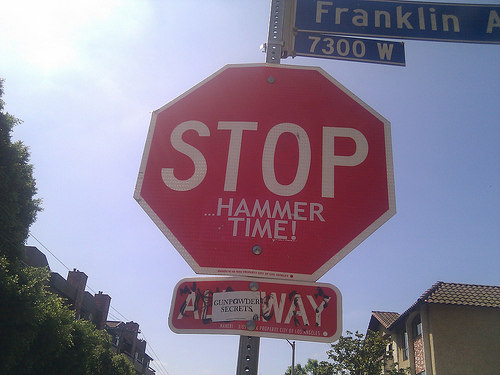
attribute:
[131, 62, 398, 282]
sign — red, white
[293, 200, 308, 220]
letter e — white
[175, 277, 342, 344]
sign — rectangular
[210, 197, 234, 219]
letter — white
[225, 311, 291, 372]
post — metal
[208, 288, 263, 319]
sticker — white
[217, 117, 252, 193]
letter — white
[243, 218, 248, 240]
letter i — white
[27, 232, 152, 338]
lines — electric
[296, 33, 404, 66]
7300 — white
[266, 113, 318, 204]
letter o — white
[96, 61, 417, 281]
sign — octogonal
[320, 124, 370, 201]
letter — white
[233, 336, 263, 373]
post — metal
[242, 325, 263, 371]
pole — silver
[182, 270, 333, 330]
marks — black